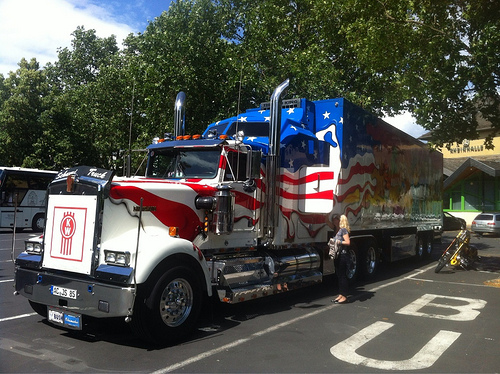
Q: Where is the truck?
A: In the parking lot.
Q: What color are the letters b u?
A: White.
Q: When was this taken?
A: During the day.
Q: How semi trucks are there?
A: One.